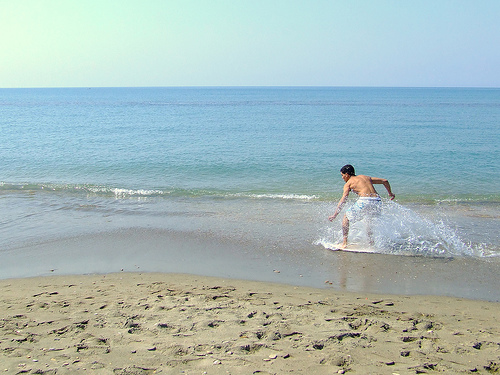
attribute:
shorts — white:
[343, 194, 383, 232]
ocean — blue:
[14, 87, 486, 161]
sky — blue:
[22, 20, 490, 73]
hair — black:
[340, 164, 355, 177]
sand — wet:
[31, 203, 292, 279]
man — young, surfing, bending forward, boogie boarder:
[325, 160, 405, 256]